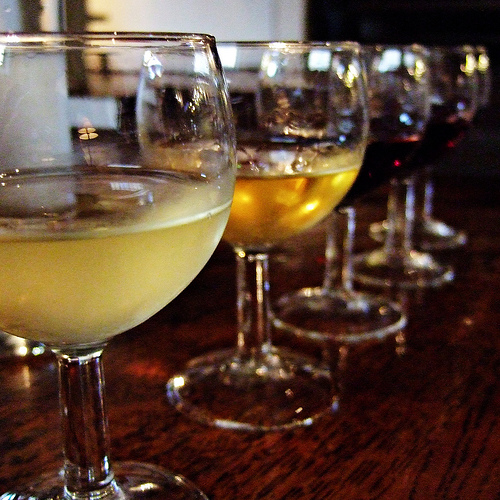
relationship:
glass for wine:
[2, 30, 238, 498] [0, 167, 236, 347]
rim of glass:
[0, 31, 216, 43] [2, 30, 238, 498]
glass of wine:
[2, 30, 238, 498] [0, 167, 236, 347]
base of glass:
[2, 458, 212, 499] [2, 30, 238, 498]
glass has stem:
[2, 30, 238, 498] [63, 339, 114, 494]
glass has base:
[2, 30, 238, 498] [2, 458, 212, 499]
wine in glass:
[0, 167, 236, 347] [2, 30, 238, 498]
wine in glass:
[150, 146, 368, 251] [136, 40, 370, 439]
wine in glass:
[269, 134, 420, 213] [253, 43, 436, 342]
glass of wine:
[253, 43, 436, 342] [269, 134, 420, 213]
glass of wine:
[341, 43, 481, 288] [403, 118, 474, 178]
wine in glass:
[403, 118, 474, 178] [341, 43, 481, 288]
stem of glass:
[63, 339, 114, 494] [2, 30, 238, 498]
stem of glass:
[236, 246, 275, 364] [136, 40, 370, 439]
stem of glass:
[323, 204, 357, 289] [253, 43, 436, 342]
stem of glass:
[389, 178, 412, 251] [341, 43, 481, 288]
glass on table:
[2, 30, 238, 498] [1, 131, 499, 499]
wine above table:
[0, 167, 236, 347] [1, 131, 499, 499]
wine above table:
[150, 146, 368, 251] [1, 131, 499, 499]